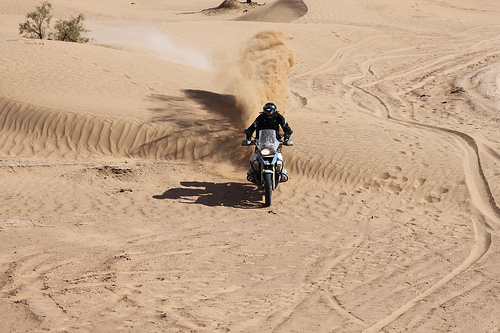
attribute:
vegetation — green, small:
[36, 4, 82, 46]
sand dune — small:
[21, 39, 132, 159]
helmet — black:
[256, 97, 280, 120]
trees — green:
[28, 4, 112, 54]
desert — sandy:
[94, 15, 470, 139]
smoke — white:
[107, 16, 236, 84]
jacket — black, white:
[244, 106, 299, 142]